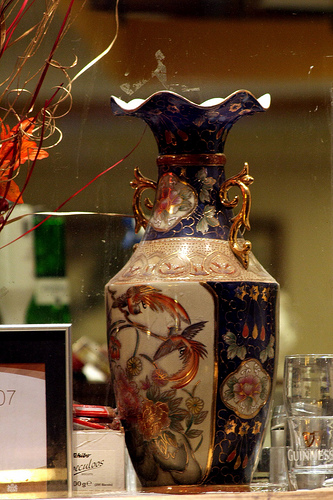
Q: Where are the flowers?
A: On vase.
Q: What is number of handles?
A: Two.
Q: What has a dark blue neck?
A: The vase top.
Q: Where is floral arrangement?
A: Next to vase.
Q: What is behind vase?
A: Mirror.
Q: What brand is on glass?
A: Guinness.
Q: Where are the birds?
A: On the vase.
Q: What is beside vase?
A: Picture frame.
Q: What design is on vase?
A: Birds and flowers.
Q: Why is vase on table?
A: Display.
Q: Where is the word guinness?
A: On glass.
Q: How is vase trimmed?
A: In gold.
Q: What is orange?
A: Flower.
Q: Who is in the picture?
A: Nobody.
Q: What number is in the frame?
A: Zero seven.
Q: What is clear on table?
A: Glasses.